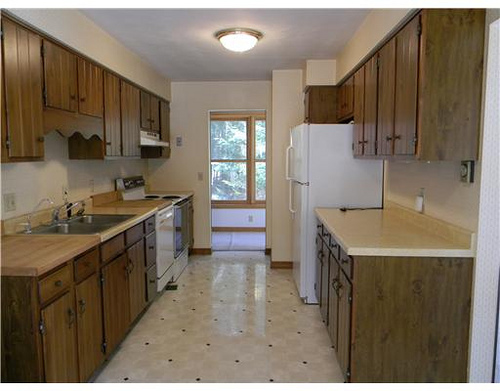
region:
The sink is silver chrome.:
[36, 192, 141, 245]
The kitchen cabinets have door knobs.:
[63, 296, 86, 319]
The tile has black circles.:
[203, 301, 283, 346]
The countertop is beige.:
[333, 203, 446, 266]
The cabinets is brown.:
[319, 65, 484, 169]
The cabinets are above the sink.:
[31, 45, 173, 160]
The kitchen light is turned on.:
[207, 19, 289, 68]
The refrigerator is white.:
[296, 127, 374, 267]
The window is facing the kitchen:
[213, 94, 272, 230]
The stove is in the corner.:
[133, 169, 212, 274]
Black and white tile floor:
[128, 250, 320, 390]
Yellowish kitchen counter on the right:
[315, 205, 475, 262]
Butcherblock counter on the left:
[2, 231, 103, 276]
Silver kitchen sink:
[36, 196, 131, 247]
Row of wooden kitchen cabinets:
[11, 182, 193, 374]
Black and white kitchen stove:
[119, 171, 199, 289]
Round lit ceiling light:
[205, 26, 272, 56]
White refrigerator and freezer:
[285, 119, 380, 307]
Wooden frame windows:
[208, 110, 274, 207]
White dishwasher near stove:
[117, 196, 189, 290]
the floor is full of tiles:
[207, 253, 285, 371]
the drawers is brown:
[50, 272, 136, 380]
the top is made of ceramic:
[333, 192, 467, 259]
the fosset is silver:
[30, 194, 120, 228]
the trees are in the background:
[218, 122, 270, 202]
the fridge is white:
[283, 126, 375, 311]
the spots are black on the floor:
[148, 256, 307, 379]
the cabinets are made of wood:
[341, 100, 458, 164]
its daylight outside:
[216, 115, 270, 199]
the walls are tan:
[173, 105, 205, 169]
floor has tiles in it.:
[182, 306, 307, 376]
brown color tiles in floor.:
[164, 307, 296, 367]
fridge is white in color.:
[282, 147, 344, 187]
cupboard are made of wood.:
[321, 273, 426, 323]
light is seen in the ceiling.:
[207, 28, 261, 63]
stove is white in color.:
[124, 176, 186, 208]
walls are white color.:
[183, 84, 210, 109]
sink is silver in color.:
[53, 213, 112, 237]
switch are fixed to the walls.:
[175, 128, 205, 196]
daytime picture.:
[211, 118, 271, 194]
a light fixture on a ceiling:
[203, 15, 278, 60]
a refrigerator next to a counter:
[276, 117, 395, 308]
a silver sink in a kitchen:
[9, 183, 150, 244]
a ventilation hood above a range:
[130, 118, 176, 162]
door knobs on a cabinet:
[63, 292, 93, 332]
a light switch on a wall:
[187, 162, 211, 189]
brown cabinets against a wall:
[346, 11, 488, 164]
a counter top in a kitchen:
[308, 190, 483, 272]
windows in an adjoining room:
[198, 105, 273, 235]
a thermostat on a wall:
[449, 152, 479, 200]